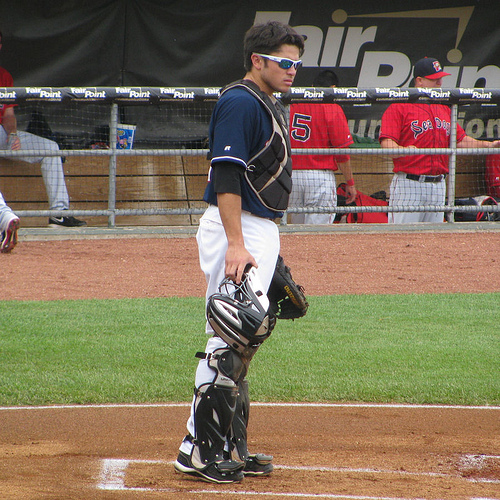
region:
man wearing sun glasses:
[227, 16, 324, 113]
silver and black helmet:
[202, 241, 281, 372]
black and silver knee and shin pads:
[165, 328, 279, 488]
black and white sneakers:
[158, 422, 233, 499]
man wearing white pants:
[180, 171, 282, 477]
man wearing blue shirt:
[205, 59, 339, 256]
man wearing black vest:
[206, 60, 315, 215]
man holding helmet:
[168, 195, 353, 391]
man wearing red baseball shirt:
[375, 57, 467, 219]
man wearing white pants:
[374, 165, 457, 229]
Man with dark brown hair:
[166, 19, 313, 480]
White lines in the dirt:
[91, 441, 498, 498]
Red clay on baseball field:
[5, 406, 496, 499]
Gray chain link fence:
[2, 81, 499, 228]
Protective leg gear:
[172, 335, 279, 481]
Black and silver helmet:
[196, 259, 276, 364]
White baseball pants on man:
[182, 192, 283, 459]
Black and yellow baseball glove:
[257, 252, 309, 332]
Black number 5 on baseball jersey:
[285, 108, 313, 150]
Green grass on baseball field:
[0, 288, 498, 420]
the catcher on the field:
[155, 15, 345, 485]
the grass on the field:
[7, 303, 497, 403]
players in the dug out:
[300, 65, 493, 228]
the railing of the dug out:
[0, 83, 490, 173]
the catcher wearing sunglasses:
[244, 48, 305, 75]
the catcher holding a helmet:
[203, 233, 291, 355]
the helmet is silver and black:
[202, 257, 284, 362]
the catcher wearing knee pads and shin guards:
[192, 337, 272, 487]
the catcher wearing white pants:
[185, 208, 288, 435]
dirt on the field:
[282, 409, 497, 497]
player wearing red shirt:
[281, 65, 356, 225]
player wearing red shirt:
[378, 55, 498, 220]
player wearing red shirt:
[3, 67, 85, 226]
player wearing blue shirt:
[172, 18, 310, 482]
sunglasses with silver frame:
[248, 52, 300, 71]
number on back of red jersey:
[285, 111, 313, 146]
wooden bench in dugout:
[0, 154, 498, 224]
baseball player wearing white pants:
[175, 20, 313, 484]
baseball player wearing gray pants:
[377, 59, 491, 225]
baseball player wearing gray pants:
[277, 68, 359, 223]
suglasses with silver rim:
[250, 47, 303, 72]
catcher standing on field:
[170, 20, 310, 476]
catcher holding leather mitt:
[165, 15, 315, 485]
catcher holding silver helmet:
[165, 21, 310, 482]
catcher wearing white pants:
[165, 15, 315, 478]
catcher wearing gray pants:
[282, 65, 354, 225]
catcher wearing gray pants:
[378, 55, 496, 220]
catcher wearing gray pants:
[0, 58, 85, 226]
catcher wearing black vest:
[167, 17, 309, 486]